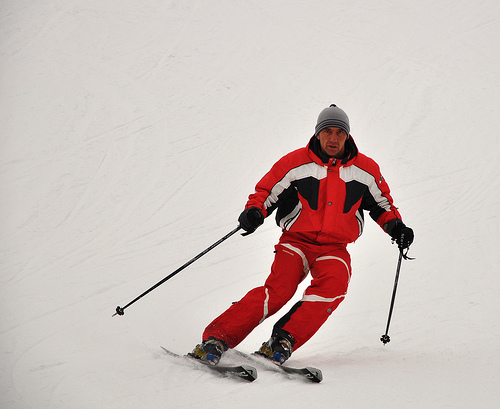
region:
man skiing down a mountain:
[96, 117, 416, 384]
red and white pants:
[200, 242, 342, 352]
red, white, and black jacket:
[253, 152, 395, 239]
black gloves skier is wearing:
[237, 209, 412, 247]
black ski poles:
[110, 212, 409, 325]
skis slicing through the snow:
[164, 339, 324, 382]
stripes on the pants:
[257, 241, 335, 343]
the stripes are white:
[312, 250, 334, 302]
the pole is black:
[390, 247, 402, 345]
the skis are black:
[179, 350, 319, 393]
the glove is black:
[242, 207, 269, 230]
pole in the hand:
[119, 202, 264, 313]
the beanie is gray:
[319, 105, 356, 137]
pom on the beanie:
[327, 102, 338, 112]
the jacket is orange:
[277, 146, 399, 243]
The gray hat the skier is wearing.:
[312, 107, 353, 129]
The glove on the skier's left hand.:
[236, 207, 259, 228]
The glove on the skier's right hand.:
[395, 230, 411, 245]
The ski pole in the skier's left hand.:
[100, 221, 264, 326]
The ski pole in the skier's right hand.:
[386, 234, 410, 348]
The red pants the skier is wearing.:
[196, 241, 353, 363]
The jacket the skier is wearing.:
[250, 141, 402, 249]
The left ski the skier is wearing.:
[156, 335, 256, 385]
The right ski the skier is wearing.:
[230, 341, 328, 382]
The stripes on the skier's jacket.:
[265, 147, 393, 227]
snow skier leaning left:
[105, 93, 418, 390]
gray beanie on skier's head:
[310, 100, 351, 138]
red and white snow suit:
[200, 136, 405, 355]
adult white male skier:
[188, 95, 420, 377]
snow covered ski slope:
[5, 3, 493, 404]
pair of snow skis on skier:
[149, 332, 327, 389]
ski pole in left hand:
[378, 232, 408, 349]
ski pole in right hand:
[102, 217, 244, 323]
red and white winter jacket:
[240, 136, 407, 245]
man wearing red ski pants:
[206, 238, 356, 349]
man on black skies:
[161, 325, 338, 387]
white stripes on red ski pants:
[257, 241, 354, 326]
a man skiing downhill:
[110, 100, 413, 384]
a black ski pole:
[110, 223, 242, 317]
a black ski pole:
[380, 244, 409, 345]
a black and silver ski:
[160, 346, 255, 380]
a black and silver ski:
[230, 345, 323, 385]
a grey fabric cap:
[314, 102, 349, 132]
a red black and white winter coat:
[243, 133, 401, 245]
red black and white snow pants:
[200, 244, 350, 349]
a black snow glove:
[237, 207, 262, 232]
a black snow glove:
[388, 218, 415, 249]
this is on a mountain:
[51, 43, 477, 297]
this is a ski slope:
[47, 30, 485, 382]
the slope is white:
[29, 83, 206, 239]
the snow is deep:
[45, 83, 196, 188]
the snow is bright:
[32, 81, 200, 238]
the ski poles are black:
[124, 195, 275, 364]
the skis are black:
[176, 316, 355, 406]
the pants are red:
[161, 240, 382, 351]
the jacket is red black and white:
[241, 129, 389, 264]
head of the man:
[283, 100, 395, 172]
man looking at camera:
[191, 85, 466, 301]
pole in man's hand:
[75, 205, 265, 352]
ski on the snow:
[148, 306, 265, 393]